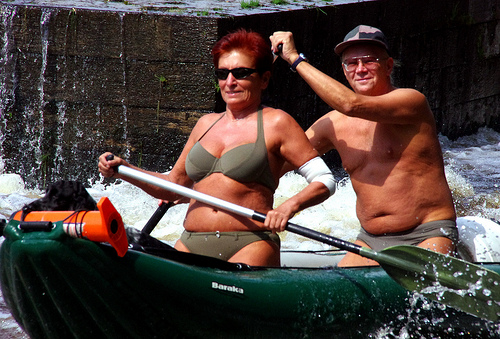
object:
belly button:
[207, 204, 226, 216]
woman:
[194, 29, 291, 262]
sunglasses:
[201, 59, 266, 81]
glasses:
[333, 53, 388, 69]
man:
[308, 17, 462, 258]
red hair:
[208, 22, 267, 69]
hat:
[322, 15, 398, 55]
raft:
[1, 225, 498, 334]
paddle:
[330, 236, 496, 329]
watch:
[293, 49, 306, 73]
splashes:
[404, 270, 480, 331]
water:
[455, 130, 500, 209]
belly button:
[363, 206, 394, 223]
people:
[139, 21, 473, 276]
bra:
[176, 122, 280, 187]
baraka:
[202, 279, 247, 298]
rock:
[23, 0, 176, 150]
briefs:
[344, 219, 451, 243]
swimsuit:
[202, 104, 272, 264]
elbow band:
[299, 154, 341, 200]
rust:
[15, 6, 46, 153]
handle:
[103, 154, 130, 175]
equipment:
[16, 188, 133, 260]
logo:
[436, 223, 452, 238]